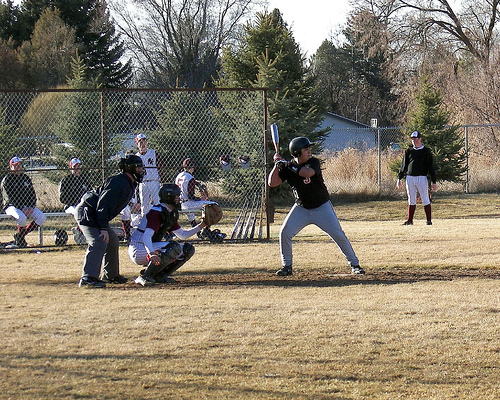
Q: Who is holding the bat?
A: Baseball player.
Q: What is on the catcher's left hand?
A: Glove.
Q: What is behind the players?
A: Fence.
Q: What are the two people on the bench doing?
A: Watching the football game.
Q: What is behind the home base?
A: A metal fence.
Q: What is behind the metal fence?
A: Trees.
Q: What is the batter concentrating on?
A: The pitch.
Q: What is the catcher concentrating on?
A: The pitch.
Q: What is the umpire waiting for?
A: The pitch.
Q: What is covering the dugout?
A: The chain link fence.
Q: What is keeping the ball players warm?
A: Long sleeved uniforms.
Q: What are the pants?
A: Grey.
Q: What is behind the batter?
A: A fence.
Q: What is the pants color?
A: White.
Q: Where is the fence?
A: Behind.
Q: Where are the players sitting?
A: Bench.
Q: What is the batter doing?
A: Swinging.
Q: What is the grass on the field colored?
A: Brown.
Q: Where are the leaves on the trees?
A: Gone.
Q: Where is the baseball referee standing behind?
A: Umpire.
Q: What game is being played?
A: Baseball.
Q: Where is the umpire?
A: Behind the catcher.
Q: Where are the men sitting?
A: On the bench.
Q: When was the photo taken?
A: During the day.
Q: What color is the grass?
A: Brown.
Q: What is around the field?
A: A fence.